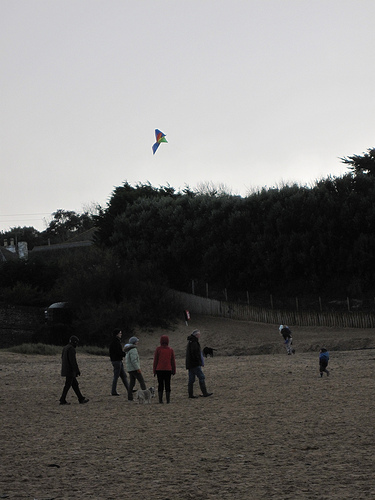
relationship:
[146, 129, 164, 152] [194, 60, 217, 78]
kite in sky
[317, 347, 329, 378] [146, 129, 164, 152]
boy are flying kite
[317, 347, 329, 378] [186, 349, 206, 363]
boy wearing black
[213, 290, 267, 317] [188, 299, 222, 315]
fence along road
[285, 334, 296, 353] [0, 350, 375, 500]
dog on beach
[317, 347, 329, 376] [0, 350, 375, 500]
boy on beach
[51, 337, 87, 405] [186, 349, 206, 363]
man wearing black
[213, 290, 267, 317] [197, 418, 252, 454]
fence on beach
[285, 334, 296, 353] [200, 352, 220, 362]
dog on leash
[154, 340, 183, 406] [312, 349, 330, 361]
girl wearing jacket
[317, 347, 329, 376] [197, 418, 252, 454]
boy on beach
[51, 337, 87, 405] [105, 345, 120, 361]
man wearing a backpack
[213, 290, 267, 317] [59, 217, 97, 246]
fence along hill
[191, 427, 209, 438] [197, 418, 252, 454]
footprints are in beach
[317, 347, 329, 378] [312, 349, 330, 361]
boy wearing jacket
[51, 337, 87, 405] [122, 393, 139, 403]
man wearing boots